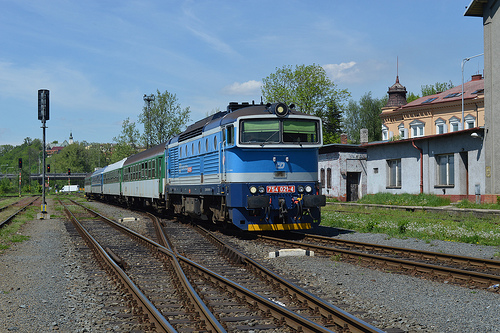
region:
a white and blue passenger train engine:
[163, 102, 330, 242]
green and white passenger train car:
[101, 142, 168, 210]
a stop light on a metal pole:
[31, 82, 56, 222]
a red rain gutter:
[408, 132, 430, 194]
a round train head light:
[273, 96, 287, 121]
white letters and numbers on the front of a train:
[263, 181, 298, 197]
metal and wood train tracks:
[53, 175, 383, 329]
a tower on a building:
[386, 52, 407, 106]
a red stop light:
[66, 168, 73, 176]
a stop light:
[10, 145, 25, 200]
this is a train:
[53, 52, 357, 309]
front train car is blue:
[148, 85, 329, 220]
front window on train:
[223, 98, 318, 156]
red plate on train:
[246, 180, 306, 202]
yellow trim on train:
[234, 202, 319, 252]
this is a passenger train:
[48, 88, 373, 255]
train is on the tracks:
[39, 52, 499, 330]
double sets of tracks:
[63, 217, 316, 330]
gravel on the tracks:
[113, 212, 413, 327]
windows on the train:
[85, 159, 188, 192]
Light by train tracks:
[35, 85, 67, 231]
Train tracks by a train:
[48, 190, 293, 331]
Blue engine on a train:
[156, 109, 338, 247]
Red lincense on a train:
[263, 182, 298, 197]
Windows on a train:
[238, 100, 328, 150]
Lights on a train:
[248, 175, 317, 201]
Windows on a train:
[108, 159, 168, 181]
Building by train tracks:
[333, 119, 492, 191]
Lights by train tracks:
[11, 142, 72, 197]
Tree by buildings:
[260, 61, 367, 142]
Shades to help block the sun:
[241, 119, 318, 136]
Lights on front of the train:
[247, 183, 312, 193]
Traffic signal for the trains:
[36, 88, 51, 121]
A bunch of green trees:
[1, 60, 463, 198]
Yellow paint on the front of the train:
[246, 222, 313, 232]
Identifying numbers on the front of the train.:
[265, 183, 296, 194]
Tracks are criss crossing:
[53, 197, 391, 332]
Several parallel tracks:
[0, 194, 499, 331]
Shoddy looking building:
[318, 126, 486, 204]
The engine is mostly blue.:
[162, 101, 328, 233]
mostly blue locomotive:
[162, 100, 325, 226]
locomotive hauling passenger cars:
[81, 107, 326, 237]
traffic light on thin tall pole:
[36, 88, 51, 210]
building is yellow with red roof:
[373, 68, 485, 140]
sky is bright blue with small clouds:
[3, 2, 460, 102]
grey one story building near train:
[315, 125, 495, 201]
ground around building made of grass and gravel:
[346, 190, 498, 238]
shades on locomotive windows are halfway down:
[231, 112, 325, 152]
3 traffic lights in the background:
[16, 155, 73, 180]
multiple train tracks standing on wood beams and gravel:
[81, 242, 498, 332]